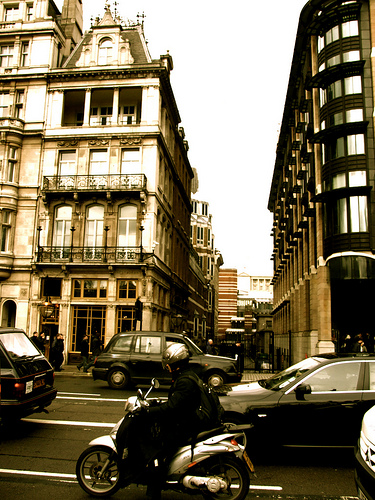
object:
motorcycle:
[72, 373, 254, 492]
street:
[7, 370, 354, 490]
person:
[127, 343, 219, 487]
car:
[86, 327, 245, 391]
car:
[205, 346, 359, 453]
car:
[5, 325, 58, 429]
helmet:
[160, 339, 189, 368]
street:
[9, 377, 351, 494]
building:
[266, 6, 362, 372]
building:
[32, 0, 177, 368]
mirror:
[293, 381, 312, 396]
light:
[12, 379, 22, 391]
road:
[6, 378, 361, 492]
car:
[213, 350, 352, 466]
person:
[140, 340, 217, 487]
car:
[4, 326, 55, 441]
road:
[4, 374, 349, 488]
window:
[50, 200, 77, 261]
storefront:
[36, 69, 155, 369]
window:
[119, 148, 144, 186]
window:
[84, 149, 111, 189]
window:
[56, 148, 76, 185]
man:
[118, 337, 208, 496]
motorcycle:
[74, 378, 260, 498]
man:
[117, 341, 198, 497]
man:
[114, 341, 206, 499]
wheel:
[77, 442, 128, 498]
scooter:
[74, 376, 256, 498]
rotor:
[91, 462, 112, 481]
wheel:
[71, 442, 124, 498]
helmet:
[160, 342, 190, 362]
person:
[114, 337, 210, 498]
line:
[0, 465, 282, 498]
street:
[1, 375, 373, 499]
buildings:
[215, 268, 274, 338]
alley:
[160, 67, 316, 373]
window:
[326, 192, 372, 237]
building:
[269, 0, 374, 378]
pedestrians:
[30, 329, 92, 372]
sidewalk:
[52, 363, 278, 383]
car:
[217, 351, 374, 454]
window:
[116, 203, 139, 257]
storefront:
[38, 195, 151, 363]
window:
[81, 200, 107, 262]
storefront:
[26, 193, 152, 366]